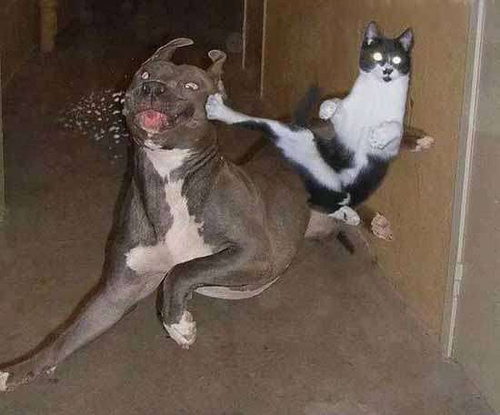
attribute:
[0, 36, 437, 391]
dog — brown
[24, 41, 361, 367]
dog — slobbering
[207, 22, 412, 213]
cat — black, white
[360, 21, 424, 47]
ears — cat's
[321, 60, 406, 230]
cat — kicking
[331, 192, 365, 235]
paw — cat's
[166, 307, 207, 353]
paw — dog's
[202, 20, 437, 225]
cat — black, white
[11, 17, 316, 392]
dog — brown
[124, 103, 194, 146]
mouth — dog's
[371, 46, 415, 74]
light — reflective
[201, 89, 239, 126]
foot — cat's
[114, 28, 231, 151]
face — dog's